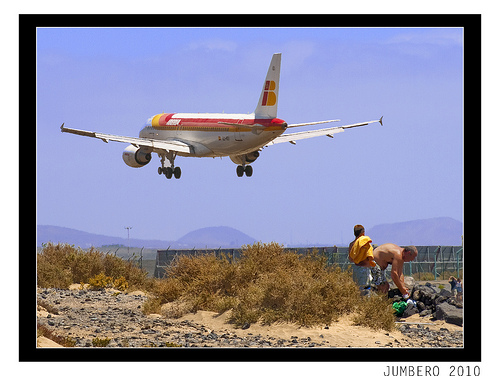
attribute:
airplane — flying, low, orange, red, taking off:
[61, 54, 384, 178]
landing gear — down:
[157, 165, 182, 182]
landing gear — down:
[235, 165, 253, 178]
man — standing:
[349, 223, 373, 296]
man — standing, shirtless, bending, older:
[371, 240, 418, 299]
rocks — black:
[384, 282, 463, 329]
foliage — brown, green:
[38, 241, 397, 332]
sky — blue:
[35, 27, 461, 247]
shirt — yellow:
[348, 236, 374, 264]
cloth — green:
[391, 296, 405, 312]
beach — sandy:
[35, 269, 465, 349]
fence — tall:
[154, 243, 464, 283]